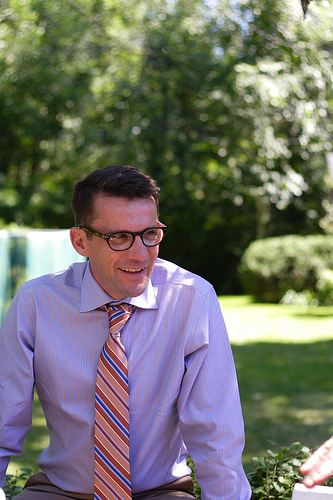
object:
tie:
[91, 300, 135, 499]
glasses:
[79, 221, 168, 251]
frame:
[78, 224, 108, 240]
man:
[4, 165, 254, 496]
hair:
[66, 163, 162, 224]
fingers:
[314, 458, 333, 484]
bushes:
[237, 235, 292, 302]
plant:
[247, 435, 319, 499]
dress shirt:
[3, 252, 254, 499]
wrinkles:
[107, 257, 114, 282]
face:
[97, 195, 163, 296]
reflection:
[159, 256, 176, 279]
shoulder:
[153, 261, 230, 319]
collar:
[76, 260, 161, 314]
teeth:
[125, 269, 128, 271]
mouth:
[115, 262, 150, 277]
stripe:
[101, 346, 129, 385]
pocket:
[170, 475, 196, 491]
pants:
[7, 470, 200, 500]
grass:
[215, 297, 332, 465]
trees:
[6, 2, 65, 230]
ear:
[70, 227, 88, 258]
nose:
[128, 237, 149, 262]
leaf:
[200, 24, 207, 44]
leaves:
[287, 261, 304, 272]